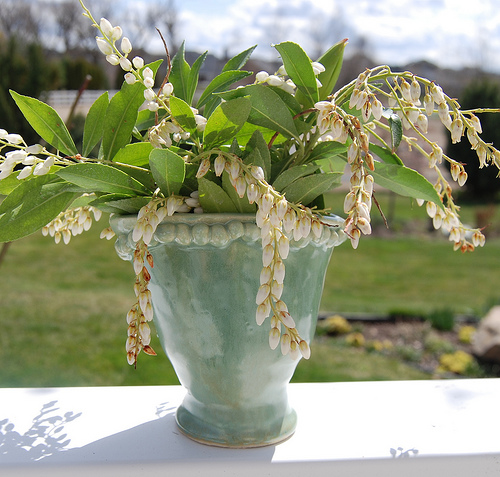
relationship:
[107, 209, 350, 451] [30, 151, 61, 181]
vase with a flower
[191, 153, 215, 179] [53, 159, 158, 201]
pod by leaf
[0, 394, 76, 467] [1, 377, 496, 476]
shadow on ledge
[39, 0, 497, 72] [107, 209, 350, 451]
sky behind vase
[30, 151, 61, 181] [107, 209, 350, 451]
flower fills vase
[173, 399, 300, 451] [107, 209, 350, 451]
base of vase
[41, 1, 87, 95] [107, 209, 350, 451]
tree behind vase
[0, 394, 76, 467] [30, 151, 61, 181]
shadow of flower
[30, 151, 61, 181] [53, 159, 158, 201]
flower by leaf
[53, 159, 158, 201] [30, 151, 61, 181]
leaf of flower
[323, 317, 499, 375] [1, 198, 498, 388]
garden in yard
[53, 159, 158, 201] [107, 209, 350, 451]
leaf in vase